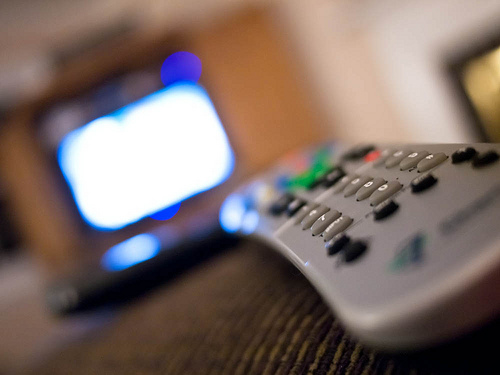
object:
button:
[369, 179, 404, 207]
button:
[353, 178, 388, 199]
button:
[370, 198, 398, 221]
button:
[322, 231, 354, 252]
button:
[448, 143, 476, 164]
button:
[472, 145, 498, 172]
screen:
[58, 81, 234, 231]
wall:
[225, 0, 328, 114]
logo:
[434, 191, 497, 233]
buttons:
[330, 166, 354, 194]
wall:
[325, 1, 450, 86]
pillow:
[38, 240, 495, 371]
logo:
[387, 231, 425, 265]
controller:
[219, 134, 498, 348]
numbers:
[289, 146, 441, 242]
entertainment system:
[27, 55, 233, 290]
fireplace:
[395, 34, 490, 132]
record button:
[287, 142, 339, 171]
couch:
[37, 264, 441, 373]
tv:
[39, 96, 234, 240]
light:
[109, 155, 142, 174]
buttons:
[276, 175, 292, 184]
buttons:
[293, 197, 315, 224]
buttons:
[360, 151, 381, 165]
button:
[343, 241, 365, 266]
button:
[346, 169, 363, 192]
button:
[406, 152, 444, 173]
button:
[323, 215, 344, 242]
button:
[355, 178, 381, 193]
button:
[269, 194, 289, 216]